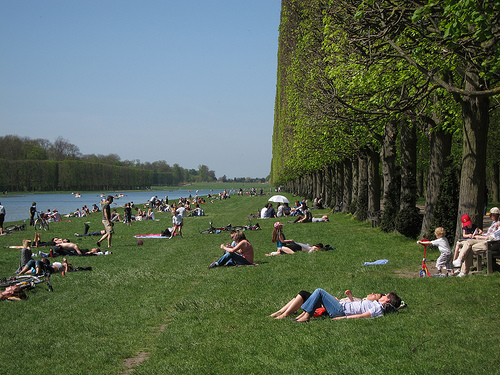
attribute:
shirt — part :
[354, 300, 377, 314]